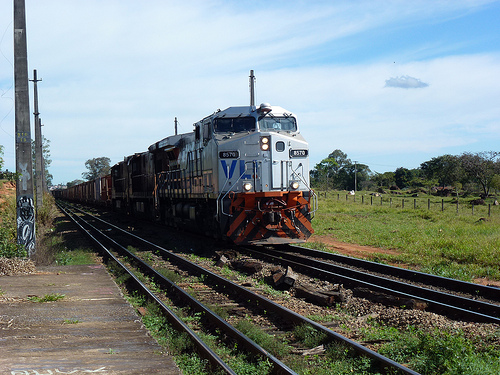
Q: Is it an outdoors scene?
A: Yes, it is outdoors.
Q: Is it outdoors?
A: Yes, it is outdoors.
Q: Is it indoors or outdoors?
A: It is outdoors.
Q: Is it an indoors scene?
A: No, it is outdoors.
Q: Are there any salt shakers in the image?
A: No, there are no salt shakers.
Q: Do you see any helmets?
A: No, there are no helmets.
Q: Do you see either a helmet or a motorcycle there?
A: No, there are no helmets or motorcycles.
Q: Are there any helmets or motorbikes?
A: No, there are no helmets or motorbikes.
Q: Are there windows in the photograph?
A: Yes, there is a window.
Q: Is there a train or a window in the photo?
A: Yes, there is a window.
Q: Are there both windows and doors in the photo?
A: No, there is a window but no doors.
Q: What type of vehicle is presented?
A: The vehicle is a car.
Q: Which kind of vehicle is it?
A: The vehicle is a car.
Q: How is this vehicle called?
A: This is a car.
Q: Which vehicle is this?
A: This is a car.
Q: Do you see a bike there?
A: No, there are no bikes.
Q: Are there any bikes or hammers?
A: No, there are no bikes or hammers.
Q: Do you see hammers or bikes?
A: No, there are no bikes or hammers.